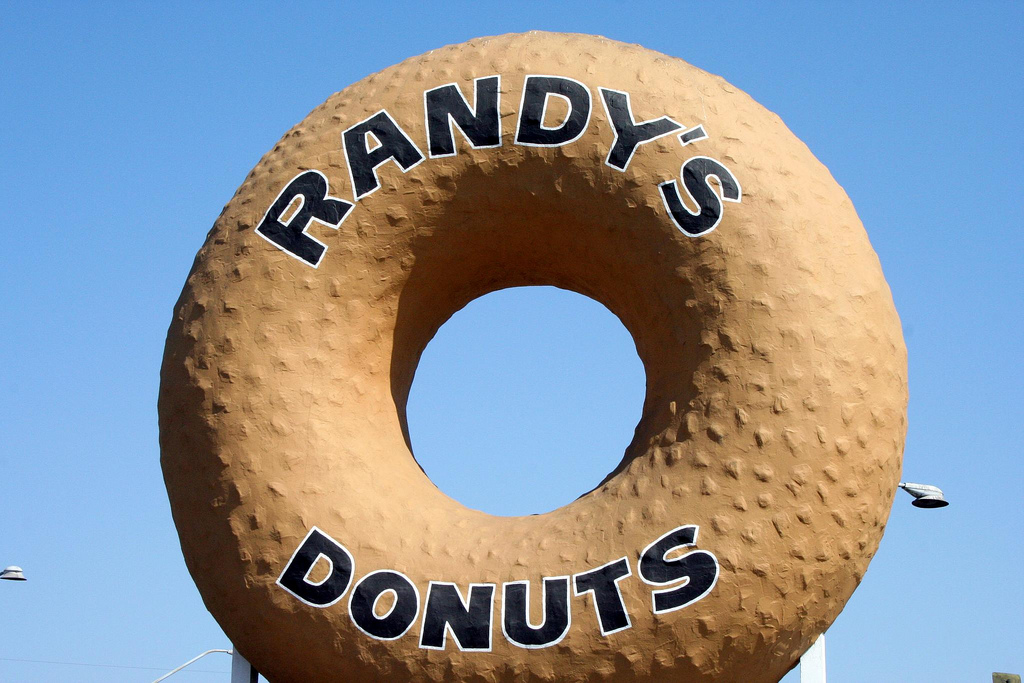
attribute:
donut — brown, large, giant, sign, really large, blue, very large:
[156, 26, 905, 681]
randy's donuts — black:
[254, 77, 740, 652]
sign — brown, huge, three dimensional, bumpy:
[158, 30, 910, 681]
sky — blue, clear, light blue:
[403, 283, 647, 519]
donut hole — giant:
[405, 284, 645, 520]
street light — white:
[1, 563, 28, 584]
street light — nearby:
[895, 474, 950, 509]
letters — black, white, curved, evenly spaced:
[255, 73, 740, 653]